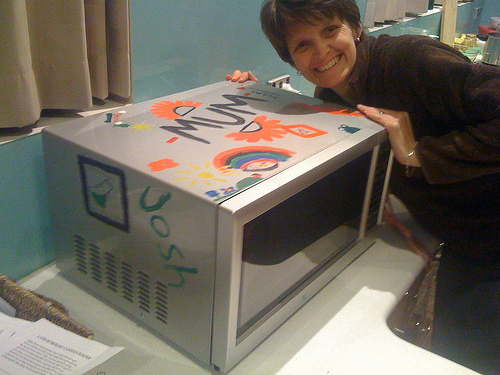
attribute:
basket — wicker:
[0, 269, 94, 374]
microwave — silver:
[38, 78, 393, 373]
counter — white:
[0, 190, 487, 372]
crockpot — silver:
[481, 32, 498, 64]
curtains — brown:
[7, 3, 134, 123]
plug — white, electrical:
[269, 61, 310, 116]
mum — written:
[160, 92, 266, 143]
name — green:
[138, 179, 200, 292]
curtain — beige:
[48, 25, 125, 75]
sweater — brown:
[385, 38, 491, 148]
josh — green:
[128, 172, 213, 299]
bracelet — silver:
[402, 143, 418, 170]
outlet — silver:
[267, 73, 295, 93]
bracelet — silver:
[403, 145, 423, 177]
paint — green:
[135, 185, 164, 223]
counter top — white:
[366, 276, 401, 360]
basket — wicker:
[4, 268, 109, 364]